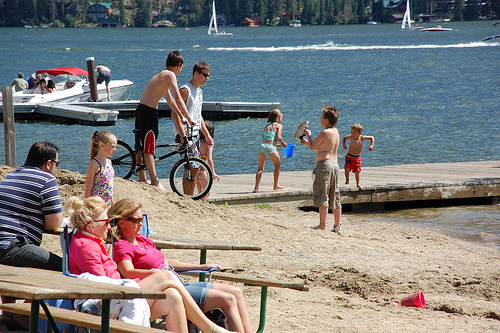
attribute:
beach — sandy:
[3, 164, 497, 332]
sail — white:
[205, 2, 230, 37]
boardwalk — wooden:
[158, 162, 499, 205]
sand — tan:
[70, 178, 499, 331]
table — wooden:
[3, 259, 168, 326]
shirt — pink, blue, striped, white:
[71, 233, 166, 280]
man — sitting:
[134, 51, 192, 188]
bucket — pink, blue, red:
[282, 142, 299, 159]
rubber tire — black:
[171, 155, 214, 204]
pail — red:
[402, 291, 429, 309]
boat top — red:
[12, 66, 134, 105]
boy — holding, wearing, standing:
[298, 106, 347, 226]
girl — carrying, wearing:
[253, 109, 295, 198]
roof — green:
[86, 3, 115, 16]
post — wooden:
[6, 88, 29, 166]